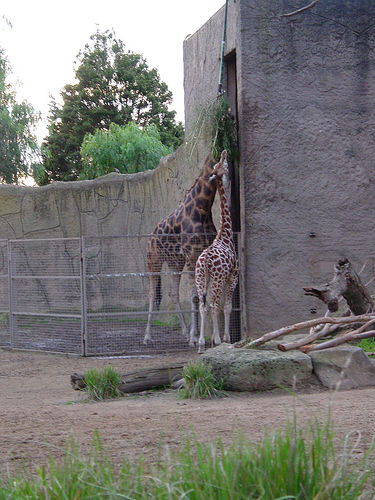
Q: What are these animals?
A: Giraffes.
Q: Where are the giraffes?
A: Zoo.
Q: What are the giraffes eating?
A: Tree leaves.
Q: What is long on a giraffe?
A: Neck.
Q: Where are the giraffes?
A: Zoo.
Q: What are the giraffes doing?
A: Eating.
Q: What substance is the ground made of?
A: Dirt.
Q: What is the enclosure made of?
A: Concrete.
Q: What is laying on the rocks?
A: Limbs.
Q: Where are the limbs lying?
A: On rocks.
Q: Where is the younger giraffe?
A: Nearest the camera.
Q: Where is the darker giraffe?
A: The other side of the fence.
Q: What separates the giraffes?
A: Fence.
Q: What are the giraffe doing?
A: Eating.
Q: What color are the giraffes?
A: Brown.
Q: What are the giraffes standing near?
A: Building.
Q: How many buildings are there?
A: One.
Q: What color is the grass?
A: Green.